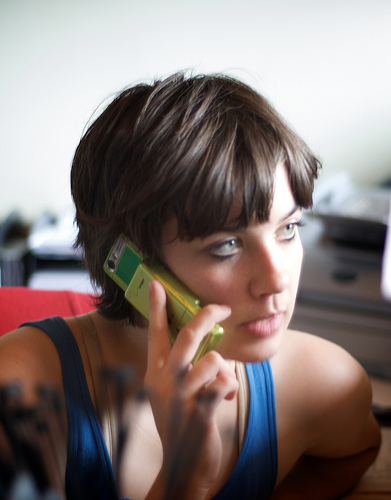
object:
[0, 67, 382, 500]
woman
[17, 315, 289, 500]
shirt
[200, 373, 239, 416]
finger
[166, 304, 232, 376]
finger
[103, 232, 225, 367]
cell phone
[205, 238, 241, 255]
eye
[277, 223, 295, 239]
eye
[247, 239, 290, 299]
nose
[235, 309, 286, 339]
mouth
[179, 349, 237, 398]
finger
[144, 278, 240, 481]
hand